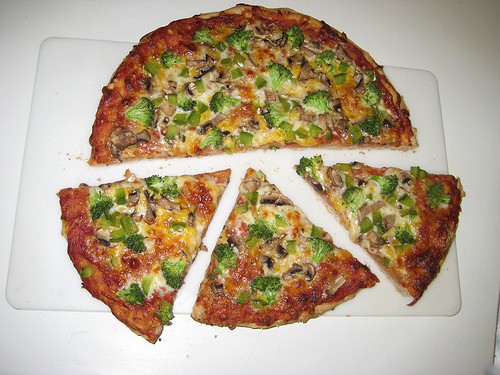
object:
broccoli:
[371, 172, 399, 195]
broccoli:
[426, 180, 451, 205]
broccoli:
[343, 185, 364, 209]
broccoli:
[300, 156, 320, 178]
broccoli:
[397, 226, 413, 246]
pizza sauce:
[234, 253, 264, 280]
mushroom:
[306, 262, 316, 281]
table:
[0, 1, 499, 374]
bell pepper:
[186, 112, 202, 129]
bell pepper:
[167, 93, 180, 106]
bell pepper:
[144, 61, 160, 75]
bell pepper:
[163, 125, 179, 140]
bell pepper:
[195, 77, 204, 95]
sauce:
[113, 99, 130, 129]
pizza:
[54, 166, 230, 343]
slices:
[51, 151, 474, 351]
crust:
[437, 169, 460, 261]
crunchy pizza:
[57, 185, 97, 260]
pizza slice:
[302, 148, 466, 304]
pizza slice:
[189, 165, 381, 330]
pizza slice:
[35, 164, 231, 346]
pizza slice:
[292, 154, 470, 306]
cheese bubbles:
[232, 65, 258, 119]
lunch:
[58, 2, 465, 344]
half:
[85, 5, 419, 163]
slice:
[190, 167, 380, 329]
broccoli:
[215, 67, 339, 125]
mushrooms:
[176, 73, 296, 140]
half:
[58, 162, 463, 334]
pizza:
[90, 10, 452, 327]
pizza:
[58, 5, 465, 347]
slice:
[301, 147, 467, 295]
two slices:
[185, 163, 472, 335]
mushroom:
[251, 235, 293, 261]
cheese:
[156, 212, 197, 249]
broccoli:
[342, 167, 404, 215]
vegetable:
[300, 89, 332, 116]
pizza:
[88, 8, 414, 151]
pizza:
[190, 167, 380, 329]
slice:
[30, 147, 218, 345]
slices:
[205, 142, 471, 344]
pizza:
[215, 152, 454, 356]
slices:
[24, 163, 492, 344]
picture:
[45, 11, 480, 365]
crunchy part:
[58, 180, 110, 261]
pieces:
[11, 5, 489, 356]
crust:
[191, 168, 378, 326]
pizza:
[299, 157, 459, 304]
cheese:
[91, 172, 221, 301]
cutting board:
[5, 34, 462, 319]